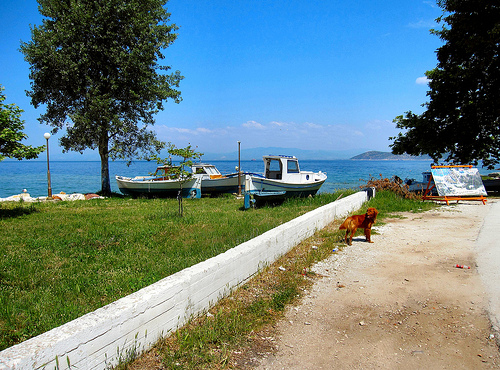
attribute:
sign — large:
[431, 154, 495, 209]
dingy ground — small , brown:
[270, 202, 494, 369]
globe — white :
[44, 132, 52, 139]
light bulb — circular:
[42, 130, 49, 140]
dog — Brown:
[336, 204, 378, 246]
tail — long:
[341, 218, 353, 229]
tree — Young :
[160, 145, 205, 220]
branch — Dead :
[361, 173, 423, 200]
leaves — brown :
[357, 172, 420, 202]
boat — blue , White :
[234, 144, 321, 208]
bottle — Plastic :
[452, 260, 474, 272]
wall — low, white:
[1, 188, 376, 364]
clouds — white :
[187, 108, 389, 153]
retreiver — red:
[342, 206, 459, 268]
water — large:
[169, 106, 427, 200]